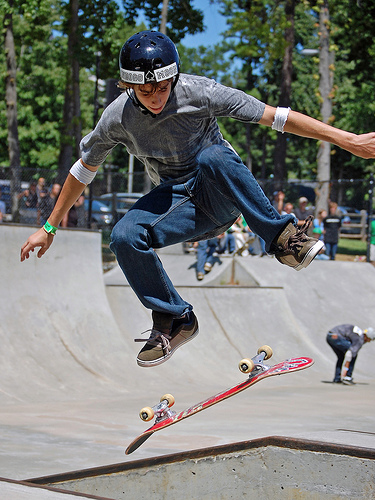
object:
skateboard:
[113, 344, 312, 458]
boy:
[16, 30, 373, 366]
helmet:
[112, 28, 181, 86]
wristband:
[41, 217, 61, 240]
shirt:
[81, 71, 267, 186]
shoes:
[135, 302, 200, 370]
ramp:
[0, 226, 375, 498]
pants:
[106, 143, 296, 318]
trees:
[310, 1, 374, 215]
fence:
[2, 159, 374, 260]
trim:
[119, 64, 179, 87]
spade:
[143, 66, 155, 85]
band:
[270, 96, 289, 137]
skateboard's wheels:
[237, 355, 256, 373]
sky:
[53, 5, 306, 95]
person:
[319, 315, 374, 387]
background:
[0, 0, 373, 498]